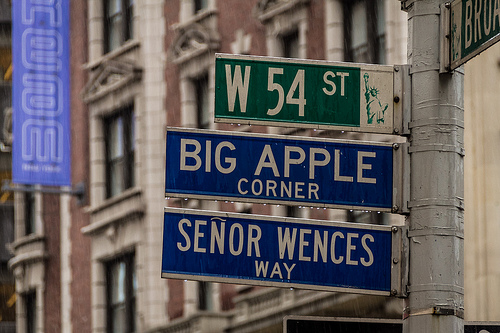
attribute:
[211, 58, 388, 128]
sign — green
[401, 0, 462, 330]
pole — metal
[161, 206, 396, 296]
street sign — blue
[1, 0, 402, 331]
building — brick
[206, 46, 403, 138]
street sign — green, white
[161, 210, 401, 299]
sign — blue, street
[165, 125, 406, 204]
sign — blue, street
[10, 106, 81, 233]
banner — blue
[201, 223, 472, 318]
font — white